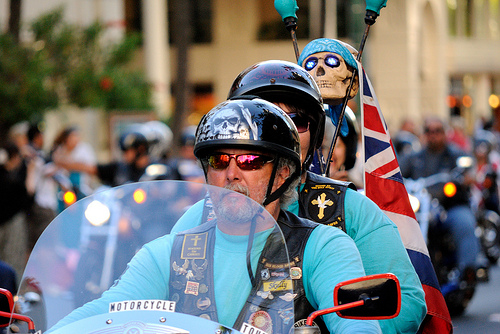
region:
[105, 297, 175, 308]
the word MOTORCYCLE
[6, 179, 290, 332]
the windshield on the motorcycle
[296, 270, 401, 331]
the left side mirror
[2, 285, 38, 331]
the right side mirror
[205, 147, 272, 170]
the man's sunglasses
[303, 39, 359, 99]
the skull in the back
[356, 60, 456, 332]
the flag in the back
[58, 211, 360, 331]
the man's blue shirt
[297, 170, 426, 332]
the woman's blue shirt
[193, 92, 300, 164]
the man's black helmet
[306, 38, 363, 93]
skull on the back of the bike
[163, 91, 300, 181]
helmet on the man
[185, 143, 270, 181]
sunglasses on the man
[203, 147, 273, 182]
reflection in the sunglasses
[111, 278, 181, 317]
words on front of bike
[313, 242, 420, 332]
mirror on the side of bike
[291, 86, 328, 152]
lady wearing sunglasses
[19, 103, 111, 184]
people in the background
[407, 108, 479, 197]
blurry person on a bike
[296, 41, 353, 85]
skull with blue bandana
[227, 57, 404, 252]
the helmet is black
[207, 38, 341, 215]
the helmet is black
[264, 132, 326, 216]
the helmet is black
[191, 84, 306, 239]
the helmet is black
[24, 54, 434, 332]
Two people on a motorcycle.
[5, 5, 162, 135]
A tree in the background.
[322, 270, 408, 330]
Side mirrors which are black and framed in red.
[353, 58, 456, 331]
A flag.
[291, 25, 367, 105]
A skeletons head.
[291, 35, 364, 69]
A blue bandana wrapped around a skeleton head.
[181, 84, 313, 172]
A black helmet with a skull on it.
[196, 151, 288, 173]
A pair of sunglasses.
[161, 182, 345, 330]
Decals on the vests.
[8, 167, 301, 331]
The windshield of a motorcycle.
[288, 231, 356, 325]
a man in blue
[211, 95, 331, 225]
a man in blue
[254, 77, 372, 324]
a man in blue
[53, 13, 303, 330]
a man in blue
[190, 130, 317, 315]
a man in blue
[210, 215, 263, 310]
a man in blue